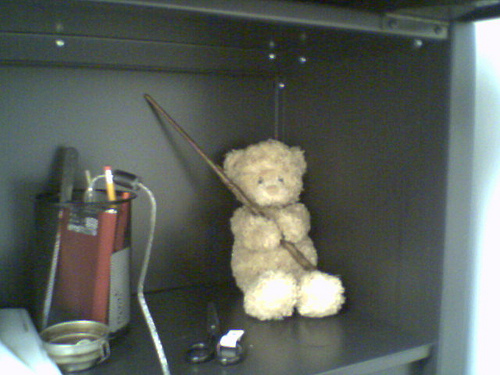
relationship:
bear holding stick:
[213, 136, 349, 324] [132, 98, 224, 184]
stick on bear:
[132, 98, 224, 184] [213, 136, 349, 324]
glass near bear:
[54, 192, 150, 338] [213, 136, 349, 324]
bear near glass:
[213, 136, 349, 324] [54, 192, 150, 338]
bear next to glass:
[213, 136, 349, 324] [54, 192, 150, 338]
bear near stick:
[213, 136, 349, 324] [132, 98, 224, 184]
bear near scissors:
[213, 136, 349, 324] [198, 308, 257, 374]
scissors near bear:
[198, 308, 257, 374] [213, 136, 349, 324]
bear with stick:
[213, 136, 349, 324] [132, 98, 224, 184]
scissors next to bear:
[198, 308, 257, 374] [213, 136, 349, 324]